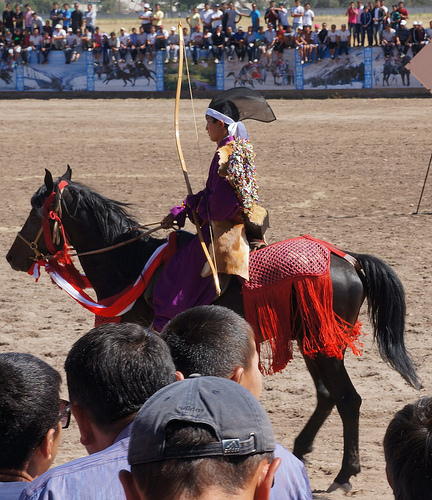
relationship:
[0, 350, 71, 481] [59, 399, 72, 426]
person wearing glasses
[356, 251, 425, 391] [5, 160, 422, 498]
tail of horse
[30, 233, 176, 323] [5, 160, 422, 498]
ribbons on horse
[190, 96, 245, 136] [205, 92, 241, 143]
white bandana around person's head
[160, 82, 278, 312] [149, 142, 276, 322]
person wearing dress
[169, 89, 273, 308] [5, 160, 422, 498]
person riding horse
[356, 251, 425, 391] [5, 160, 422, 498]
tail on horse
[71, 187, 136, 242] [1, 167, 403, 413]
mane on horse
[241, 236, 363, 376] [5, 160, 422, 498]
blanket on horse